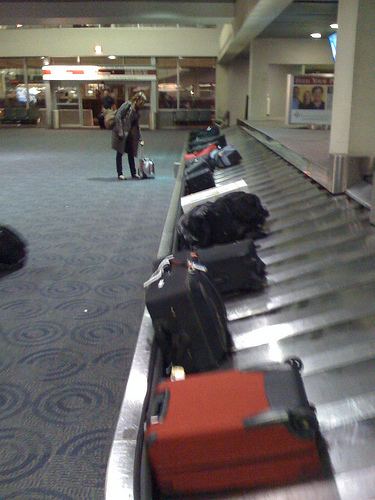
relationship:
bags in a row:
[179, 152, 264, 292] [183, 154, 258, 291]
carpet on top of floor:
[62, 204, 133, 255] [22, 152, 80, 197]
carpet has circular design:
[62, 204, 133, 255] [27, 348, 89, 384]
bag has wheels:
[146, 356, 333, 485] [281, 354, 321, 433]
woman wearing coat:
[112, 87, 159, 189] [120, 102, 143, 151]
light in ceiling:
[312, 30, 328, 43] [296, 9, 333, 30]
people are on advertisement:
[297, 85, 328, 110] [292, 74, 336, 129]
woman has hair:
[112, 87, 159, 189] [136, 93, 146, 107]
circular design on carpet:
[27, 348, 89, 384] [62, 204, 133, 255]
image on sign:
[297, 85, 328, 110] [292, 74, 336, 129]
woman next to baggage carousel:
[112, 87, 159, 189] [181, 124, 370, 292]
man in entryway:
[101, 89, 113, 111] [90, 79, 124, 128]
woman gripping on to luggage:
[112, 87, 159, 189] [138, 139, 156, 181]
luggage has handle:
[138, 139, 156, 181] [142, 139, 147, 157]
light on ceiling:
[312, 30, 328, 43] [296, 9, 333, 30]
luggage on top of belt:
[185, 139, 219, 159] [241, 140, 281, 182]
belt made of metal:
[241, 140, 281, 182] [258, 161, 311, 205]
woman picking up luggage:
[112, 87, 159, 189] [138, 139, 156, 181]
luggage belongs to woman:
[138, 139, 156, 181] [112, 87, 159, 189]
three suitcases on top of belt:
[157, 208, 267, 355] [241, 156, 277, 182]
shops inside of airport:
[7, 73, 65, 107] [24, 19, 366, 125]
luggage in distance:
[185, 139, 219, 159] [188, 143, 233, 164]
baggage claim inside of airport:
[167, 107, 374, 495] [24, 19, 366, 125]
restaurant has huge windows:
[28, 84, 81, 111] [6, 60, 30, 113]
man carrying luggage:
[101, 89, 113, 111] [96, 110, 106, 129]